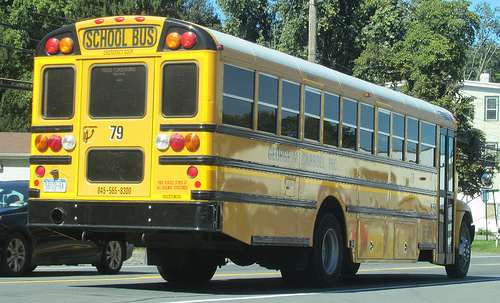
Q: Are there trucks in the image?
A: No, there are no trucks.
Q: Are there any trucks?
A: No, there are no trucks.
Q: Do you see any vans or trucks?
A: No, there are no trucks or vans.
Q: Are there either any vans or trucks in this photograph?
A: No, there are no trucks or vans.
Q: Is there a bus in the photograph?
A: Yes, there is a bus.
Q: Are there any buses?
A: Yes, there is a bus.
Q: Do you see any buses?
A: Yes, there is a bus.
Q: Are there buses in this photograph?
A: Yes, there is a bus.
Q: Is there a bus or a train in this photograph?
A: Yes, there is a bus.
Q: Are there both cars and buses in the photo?
A: Yes, there are both a bus and a car.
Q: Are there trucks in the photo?
A: No, there are no trucks.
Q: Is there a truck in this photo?
A: No, there are no trucks.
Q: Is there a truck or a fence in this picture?
A: No, there are no trucks or fences.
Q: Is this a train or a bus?
A: This is a bus.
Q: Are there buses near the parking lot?
A: Yes, there is a bus near the parking lot.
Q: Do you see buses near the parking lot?
A: Yes, there is a bus near the parking lot.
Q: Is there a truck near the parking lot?
A: No, there is a bus near the parking lot.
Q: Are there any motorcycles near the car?
A: No, there is a bus near the car.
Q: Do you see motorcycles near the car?
A: No, there is a bus near the car.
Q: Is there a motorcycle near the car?
A: No, there is a bus near the car.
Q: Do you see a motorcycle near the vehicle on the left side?
A: No, there is a bus near the car.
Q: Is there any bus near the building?
A: Yes, there is a bus near the building.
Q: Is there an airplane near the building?
A: No, there is a bus near the building.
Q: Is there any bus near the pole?
A: Yes, there is a bus near the pole.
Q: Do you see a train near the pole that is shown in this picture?
A: No, there is a bus near the pole.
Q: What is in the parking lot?
A: The bus is in the parking lot.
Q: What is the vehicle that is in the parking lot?
A: The vehicle is a bus.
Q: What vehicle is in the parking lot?
A: The vehicle is a bus.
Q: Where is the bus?
A: The bus is in the parking lot.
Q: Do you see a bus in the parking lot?
A: Yes, there is a bus in the parking lot.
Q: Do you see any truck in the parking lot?
A: No, there is a bus in the parking lot.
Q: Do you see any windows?
A: Yes, there is a window.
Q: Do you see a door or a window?
A: Yes, there is a window.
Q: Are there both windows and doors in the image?
A: Yes, there are both a window and a door.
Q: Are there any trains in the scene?
A: No, there are no trains.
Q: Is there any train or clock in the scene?
A: No, there are no trains or clocks.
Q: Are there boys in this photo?
A: No, there are no boys.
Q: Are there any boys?
A: No, there are no boys.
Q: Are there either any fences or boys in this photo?
A: No, there are no boys or fences.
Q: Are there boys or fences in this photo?
A: No, there are no boys or fences.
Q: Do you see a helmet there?
A: No, there are no helmets.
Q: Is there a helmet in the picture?
A: No, there are no helmets.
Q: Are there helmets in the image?
A: No, there are no helmets.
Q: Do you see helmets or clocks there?
A: No, there are no helmets or clocks.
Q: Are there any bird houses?
A: No, there are no bird houses.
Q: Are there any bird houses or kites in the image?
A: No, there are no bird houses or kites.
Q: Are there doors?
A: Yes, there is a door.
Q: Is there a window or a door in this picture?
A: Yes, there is a door.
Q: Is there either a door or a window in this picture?
A: Yes, there is a door.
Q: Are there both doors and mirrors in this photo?
A: No, there is a door but no mirrors.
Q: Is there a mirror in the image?
A: No, there are no mirrors.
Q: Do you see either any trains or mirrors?
A: No, there are no mirrors or trains.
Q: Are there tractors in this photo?
A: No, there are no tractors.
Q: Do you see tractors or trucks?
A: No, there are no tractors or trucks.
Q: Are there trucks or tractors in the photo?
A: No, there are no tractors or trucks.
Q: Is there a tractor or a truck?
A: No, there are no tractors or trucks.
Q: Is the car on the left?
A: Yes, the car is on the left of the image.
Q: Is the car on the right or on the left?
A: The car is on the left of the image.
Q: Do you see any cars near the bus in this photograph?
A: Yes, there is a car near the bus.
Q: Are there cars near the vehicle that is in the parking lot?
A: Yes, there is a car near the bus.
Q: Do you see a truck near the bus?
A: No, there is a car near the bus.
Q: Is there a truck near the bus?
A: No, there is a car near the bus.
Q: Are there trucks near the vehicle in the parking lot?
A: No, there is a car near the bus.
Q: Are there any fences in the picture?
A: No, there are no fences.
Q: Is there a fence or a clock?
A: No, there are no fences or clocks.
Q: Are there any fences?
A: No, there are no fences.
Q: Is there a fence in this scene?
A: No, there are no fences.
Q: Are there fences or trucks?
A: No, there are no fences or trucks.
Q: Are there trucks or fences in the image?
A: No, there are no fences or trucks.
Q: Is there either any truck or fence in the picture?
A: No, there are no fences or trucks.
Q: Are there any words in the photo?
A: Yes, there are words.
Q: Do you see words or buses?
A: Yes, there are words.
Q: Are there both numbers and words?
A: Yes, there are both words and numbers.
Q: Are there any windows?
A: Yes, there are windows.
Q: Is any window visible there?
A: Yes, there are windows.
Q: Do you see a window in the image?
A: Yes, there are windows.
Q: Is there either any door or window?
A: Yes, there are windows.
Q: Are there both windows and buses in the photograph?
A: Yes, there are both windows and a bus.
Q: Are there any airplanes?
A: No, there are no airplanes.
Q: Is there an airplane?
A: No, there are no airplanes.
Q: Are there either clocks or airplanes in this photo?
A: No, there are no airplanes or clocks.